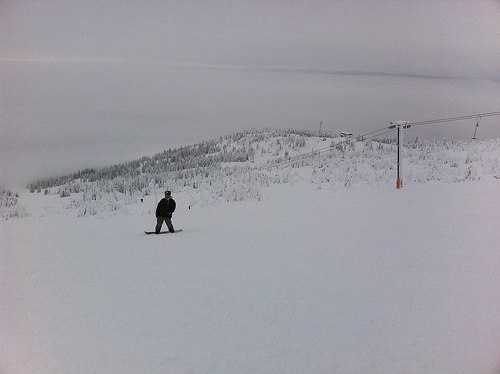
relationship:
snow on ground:
[0, 130, 498, 373] [1, 135, 485, 369]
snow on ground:
[0, 130, 498, 373] [36, 221, 475, 359]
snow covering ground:
[0, 130, 498, 373] [1, 135, 485, 369]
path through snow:
[30, 237, 376, 371] [11, 212, 499, 367]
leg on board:
[163, 216, 173, 234] [143, 226, 184, 236]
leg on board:
[156, 215, 163, 232] [143, 226, 184, 236]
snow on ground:
[6, 148, 498, 369] [2, 214, 483, 369]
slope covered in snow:
[7, 178, 497, 301] [83, 235, 380, 369]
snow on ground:
[0, 130, 498, 373] [1, 185, 496, 372]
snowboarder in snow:
[154, 187, 177, 235] [325, 227, 433, 329]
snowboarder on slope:
[144, 187, 183, 238] [196, 199, 276, 340]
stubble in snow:
[280, 143, 363, 177] [72, 67, 461, 367]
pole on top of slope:
[389, 117, 410, 189] [0, 127, 496, 239]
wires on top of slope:
[226, 109, 498, 184] [0, 127, 496, 239]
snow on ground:
[0, 130, 498, 373] [27, 154, 467, 365]